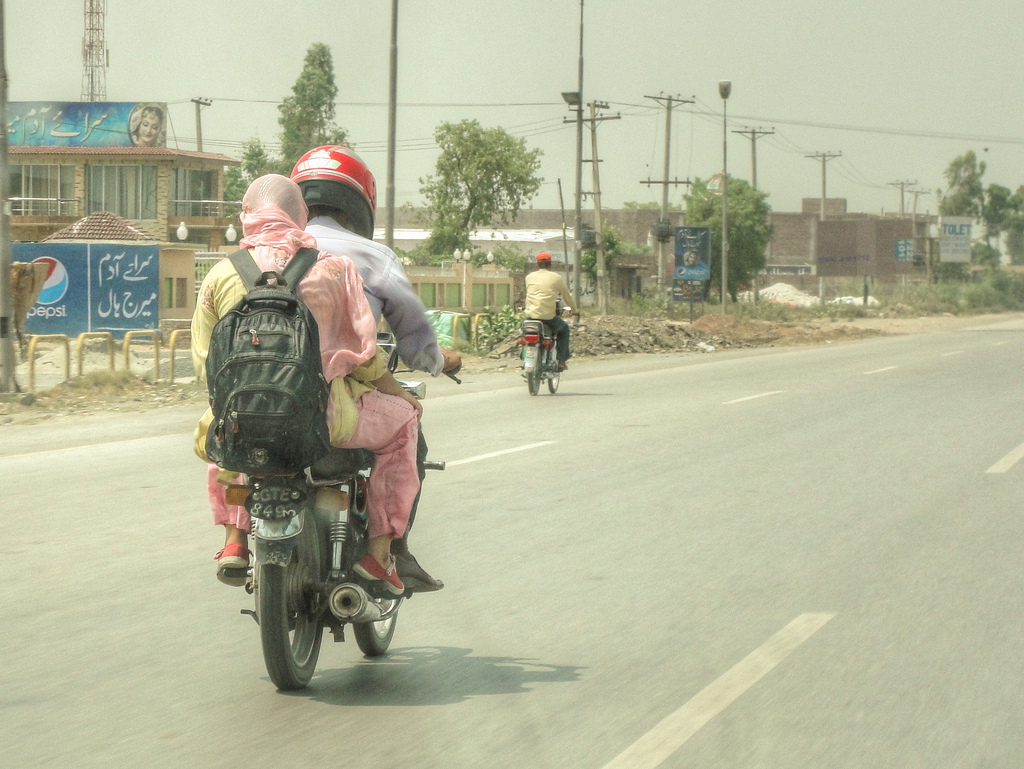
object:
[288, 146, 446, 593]
man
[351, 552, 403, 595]
shoe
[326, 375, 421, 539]
pants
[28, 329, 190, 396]
fencepoles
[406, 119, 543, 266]
tree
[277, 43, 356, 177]
tree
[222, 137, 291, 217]
tree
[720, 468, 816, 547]
ground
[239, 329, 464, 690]
motorcycle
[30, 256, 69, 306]
logo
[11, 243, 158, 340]
sign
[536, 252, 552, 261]
red hat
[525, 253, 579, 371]
man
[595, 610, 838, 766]
white lines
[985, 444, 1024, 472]
white lines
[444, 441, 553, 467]
white lines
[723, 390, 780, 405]
white lines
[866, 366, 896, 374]
white lines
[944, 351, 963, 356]
white lines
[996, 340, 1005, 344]
white lines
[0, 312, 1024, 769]
paved street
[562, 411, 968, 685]
street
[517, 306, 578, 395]
motorcycle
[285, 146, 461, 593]
person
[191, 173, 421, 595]
person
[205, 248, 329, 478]
backpack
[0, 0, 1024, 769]
city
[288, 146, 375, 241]
head